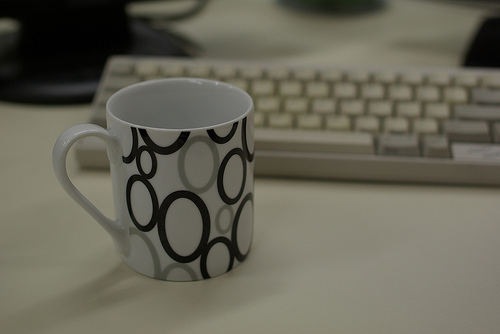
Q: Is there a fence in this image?
A: No, there are no fences.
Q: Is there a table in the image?
A: Yes, there is a table.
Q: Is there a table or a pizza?
A: Yes, there is a table.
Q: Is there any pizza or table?
A: Yes, there is a table.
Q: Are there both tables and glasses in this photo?
A: No, there is a table but no glasses.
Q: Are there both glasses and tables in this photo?
A: No, there is a table but no glasses.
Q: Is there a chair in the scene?
A: No, there are no chairs.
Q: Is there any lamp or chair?
A: No, there are no chairs or lamps.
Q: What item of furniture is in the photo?
A: The piece of furniture is a table.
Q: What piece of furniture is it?
A: The piece of furniture is a table.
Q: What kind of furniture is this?
A: That is a table.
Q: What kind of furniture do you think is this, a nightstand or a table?
A: That is a table.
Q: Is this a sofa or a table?
A: This is a table.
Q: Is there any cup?
A: Yes, there is a cup.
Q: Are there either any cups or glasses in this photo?
A: Yes, there is a cup.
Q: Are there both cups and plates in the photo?
A: No, there is a cup but no plates.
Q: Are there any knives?
A: No, there are no knives.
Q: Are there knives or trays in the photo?
A: No, there are no knives or trays.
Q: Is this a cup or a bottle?
A: This is a cup.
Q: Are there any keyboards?
A: Yes, there is a keyboard.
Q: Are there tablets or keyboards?
A: Yes, there is a keyboard.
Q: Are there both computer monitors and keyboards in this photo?
A: No, there is a keyboard but no computer monitors.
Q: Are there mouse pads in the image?
A: No, there are no mouse pads.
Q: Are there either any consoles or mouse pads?
A: No, there are no mouse pads or consoles.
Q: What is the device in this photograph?
A: The device is a keyboard.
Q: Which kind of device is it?
A: The device is a keyboard.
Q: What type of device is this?
A: This is a keyboard.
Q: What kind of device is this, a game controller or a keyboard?
A: This is a keyboard.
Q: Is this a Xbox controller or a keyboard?
A: This is a keyboard.